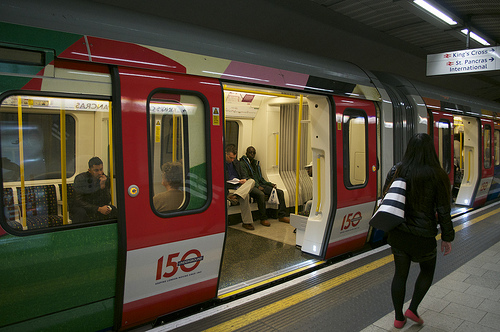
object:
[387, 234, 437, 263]
skirt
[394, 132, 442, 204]
hair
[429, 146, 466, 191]
ground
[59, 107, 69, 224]
hand rail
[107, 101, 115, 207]
hand rail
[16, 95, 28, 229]
hand rail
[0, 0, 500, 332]
subway car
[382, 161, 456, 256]
coat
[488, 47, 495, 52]
arrows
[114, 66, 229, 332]
door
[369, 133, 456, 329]
female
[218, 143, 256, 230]
man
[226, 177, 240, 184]
newspaper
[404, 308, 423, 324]
pink shoe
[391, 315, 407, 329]
pink shoe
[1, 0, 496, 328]
subway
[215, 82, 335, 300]
open door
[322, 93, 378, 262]
doors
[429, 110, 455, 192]
door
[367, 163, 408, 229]
bag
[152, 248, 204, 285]
giraffe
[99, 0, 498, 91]
ceiling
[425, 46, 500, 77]
sign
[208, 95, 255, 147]
floor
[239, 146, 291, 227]
man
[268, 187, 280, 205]
bag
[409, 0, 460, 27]
light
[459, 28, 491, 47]
light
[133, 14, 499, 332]
station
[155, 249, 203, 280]
numbers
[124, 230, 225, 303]
background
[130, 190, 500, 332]
platform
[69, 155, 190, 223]
people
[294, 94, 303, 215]
bars